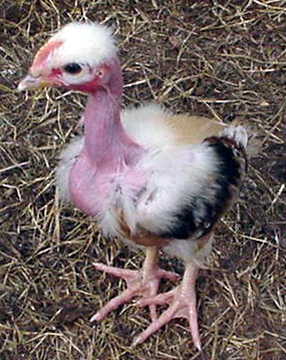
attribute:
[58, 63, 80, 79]
eye — dark colored, almond shaped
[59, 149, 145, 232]
bird breast — pink, small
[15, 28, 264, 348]
bird — baby, black, white, young, small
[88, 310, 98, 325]
nail — small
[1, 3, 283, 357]
ground — brown, grass covered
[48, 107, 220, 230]
fur — white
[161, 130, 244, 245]
fur — black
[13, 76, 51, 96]
beak — small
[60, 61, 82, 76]
eye — small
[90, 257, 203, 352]
feet — pink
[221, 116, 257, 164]
tail — tiny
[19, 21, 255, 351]
baby turkey — newly hatched, littel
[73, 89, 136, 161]
neck — bare, pink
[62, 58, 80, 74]
eye — black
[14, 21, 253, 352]
turkey — newly hatched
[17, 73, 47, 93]
beak — tiny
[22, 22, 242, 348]
duckling — ugly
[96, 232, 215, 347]
legs — thin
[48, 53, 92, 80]
eye — small black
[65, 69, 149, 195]
neck — featherless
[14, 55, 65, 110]
beak — pointy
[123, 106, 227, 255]
feathers — few downy